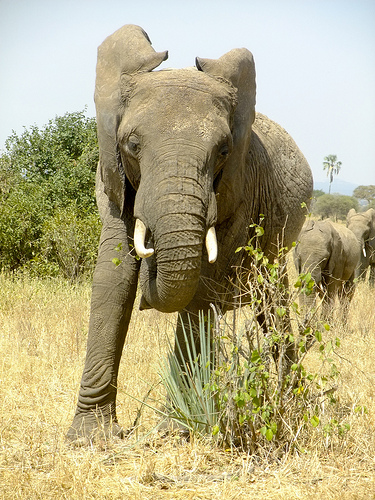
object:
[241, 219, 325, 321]
patch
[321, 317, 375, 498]
grass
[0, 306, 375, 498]
field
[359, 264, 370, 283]
trunk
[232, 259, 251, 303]
trunk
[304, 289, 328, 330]
trunk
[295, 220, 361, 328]
elephant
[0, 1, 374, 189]
sky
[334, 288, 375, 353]
grass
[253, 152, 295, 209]
wrinkles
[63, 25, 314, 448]
elephant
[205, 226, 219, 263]
tusk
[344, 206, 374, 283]
elephant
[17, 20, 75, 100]
clouds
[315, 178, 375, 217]
mountain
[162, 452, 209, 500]
grass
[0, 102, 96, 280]
bush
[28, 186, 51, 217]
leaves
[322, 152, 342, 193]
palm tree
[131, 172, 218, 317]
elephant trunk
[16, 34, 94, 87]
white clouds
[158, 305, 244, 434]
grass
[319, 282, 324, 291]
elephant tusk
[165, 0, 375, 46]
clouds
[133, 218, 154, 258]
tusk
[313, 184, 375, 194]
horizon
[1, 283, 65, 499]
grass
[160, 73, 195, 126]
skin